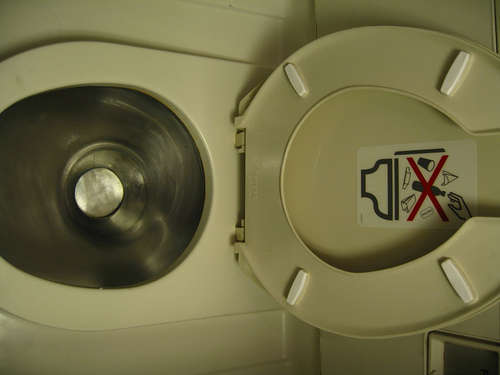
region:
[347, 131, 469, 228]
sign on the inside of a toilet lid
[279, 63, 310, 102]
white bumper on the inside of a toilet lid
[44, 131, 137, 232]
wilder toilet bowl inside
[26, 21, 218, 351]
white toilet seat lid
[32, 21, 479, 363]
toilet in an airplane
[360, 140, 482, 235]
sign of things not to throw into a toilet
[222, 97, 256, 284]
hinge on a toilet seat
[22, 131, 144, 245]
shiny inside of a toilet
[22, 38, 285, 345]
white toilet seat in an airplane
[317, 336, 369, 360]
white wall behind a toilet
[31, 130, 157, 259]
The inside of the toilet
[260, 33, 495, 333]
The top of the toilet seat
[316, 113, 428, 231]
The top to the toilet seat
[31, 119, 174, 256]
The inside of the toilet is stainless steel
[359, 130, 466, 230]
The sticker on the inside of the toilet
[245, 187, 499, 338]
One side of the toilet seat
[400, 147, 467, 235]
The "x" is in the color red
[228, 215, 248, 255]
The screw holding the toilet together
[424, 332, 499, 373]
The trash can on the wall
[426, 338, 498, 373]
The trash can is made of metal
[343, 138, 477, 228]
sign is on the toilet lid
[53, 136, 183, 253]
the toilet is silver in color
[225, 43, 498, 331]
the lid is up in the air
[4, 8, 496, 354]
the seat is in the plane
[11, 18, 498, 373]
the scene is indoors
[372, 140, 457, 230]
x sign is on the lid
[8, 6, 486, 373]
the seat is whiite in color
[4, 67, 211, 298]
the toilet is clean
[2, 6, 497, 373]
the room is well lit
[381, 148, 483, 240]
bottle and cups are on the seat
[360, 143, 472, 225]
Toilet use instruction on seat.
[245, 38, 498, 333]
Under side of toilet seat.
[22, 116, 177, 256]
Metal inside bowl of toilet.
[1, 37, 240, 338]
Vanilla colored base of toilet.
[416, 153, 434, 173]
Picture of cup on toilet.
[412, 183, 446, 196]
Picture of bottle on toilet.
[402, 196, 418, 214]
Paper bag picture on toilet backing.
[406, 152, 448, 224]
Red 'X' on toilet backing.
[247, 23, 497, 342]
Tan colored toilet seat lid.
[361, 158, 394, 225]
Picture of toilet bowl.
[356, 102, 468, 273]
a warning sticker on toilet lid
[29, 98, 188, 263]
the toilet bowl is silver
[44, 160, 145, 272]
the toilet bowl is silver